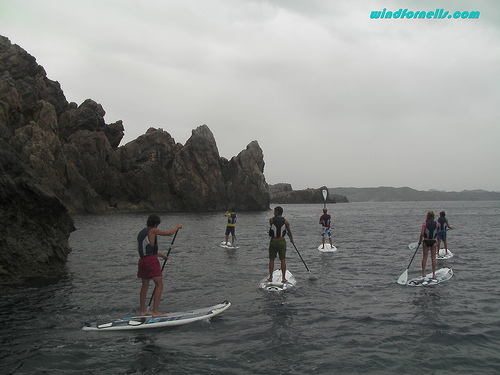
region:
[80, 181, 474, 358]
people surfing in the water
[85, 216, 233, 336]
a man standing on a surfboard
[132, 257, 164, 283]
the man is wearing red shorts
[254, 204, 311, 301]
another man to his right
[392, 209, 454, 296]
two people further right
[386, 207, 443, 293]
the woman is holding a paddle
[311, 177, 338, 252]
he is holding a paddle straight up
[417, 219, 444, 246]
the woman is wearing a pink shirt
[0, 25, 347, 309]
rocks towering over the water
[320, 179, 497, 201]
hills across the water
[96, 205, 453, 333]
group of people on paddle boards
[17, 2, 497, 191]
cloud cover in sky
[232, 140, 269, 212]
rock cliff over water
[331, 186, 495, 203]
hazy mountains on horizon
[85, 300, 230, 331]
paddle board with white edge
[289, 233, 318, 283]
oar in man's hand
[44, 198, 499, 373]
ripples on water surface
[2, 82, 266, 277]
rocky terrain over water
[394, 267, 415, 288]
white paddle of oar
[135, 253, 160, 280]
red shorts on man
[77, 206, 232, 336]
person on a paddleboard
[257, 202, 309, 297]
person on a paddleboard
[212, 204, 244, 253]
person on a paddleboard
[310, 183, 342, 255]
person on a paddleboard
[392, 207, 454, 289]
person on a paddleboard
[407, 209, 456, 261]
person on a paddleboard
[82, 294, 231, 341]
white paddleboard on the water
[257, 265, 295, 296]
white paddleboard on the water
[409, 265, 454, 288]
white paddleboard on the water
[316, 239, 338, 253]
white paddleboard on the water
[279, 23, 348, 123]
part of a cloud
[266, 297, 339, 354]
part of a water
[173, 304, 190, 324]
part of a board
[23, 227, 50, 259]
part of a cliff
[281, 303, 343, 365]
part of a wave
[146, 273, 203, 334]
part of a board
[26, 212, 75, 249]
part of a cliff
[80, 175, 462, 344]
six paddleboarders in ocean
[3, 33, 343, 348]
cliffs along ocean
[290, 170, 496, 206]
mountains in the far distance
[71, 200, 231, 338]
woman wearing pink shorts on paddleboard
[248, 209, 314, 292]
man wearing green swim trunks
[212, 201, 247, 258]
man wearing yellow shirt on white paddleboard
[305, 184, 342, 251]
man holding his paddle in the air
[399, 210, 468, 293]
two women on paddleboards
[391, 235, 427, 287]
white paddle with dark colored handle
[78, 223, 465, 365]
six white paddleboards